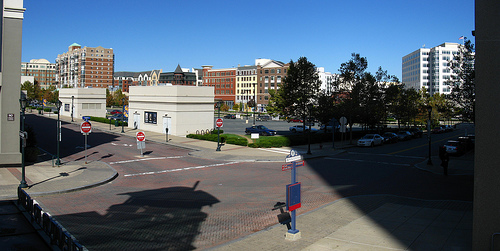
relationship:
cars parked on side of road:
[355, 115, 446, 151] [30, 114, 467, 241]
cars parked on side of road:
[444, 125, 472, 160] [30, 114, 467, 241]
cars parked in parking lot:
[244, 124, 277, 136] [215, 105, 318, 135]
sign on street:
[134, 131, 148, 141] [64, 109, 466, 239]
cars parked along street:
[355, 133, 386, 147] [306, 133, 401, 214]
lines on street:
[120, 154, 236, 178] [140, 147, 207, 232]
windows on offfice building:
[407, 53, 447, 96] [398, 39, 484, 111]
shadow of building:
[309, 127, 419, 208] [440, 15, 485, 245]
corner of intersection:
[0, 160, 120, 206] [128, 139, 254, 248]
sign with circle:
[80, 121, 94, 135] [78, 118, 92, 129]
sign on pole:
[274, 146, 298, 182] [286, 151, 313, 234]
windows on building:
[221, 69, 269, 92] [213, 49, 292, 65]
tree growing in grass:
[264, 56, 324, 132] [261, 123, 317, 148]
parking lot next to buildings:
[218, 108, 280, 147] [205, 66, 288, 114]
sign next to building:
[65, 111, 96, 176] [13, 43, 23, 184]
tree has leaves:
[264, 56, 324, 132] [283, 86, 320, 114]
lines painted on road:
[109, 140, 219, 186] [134, 169, 216, 240]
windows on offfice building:
[411, 54, 461, 97] [402, 41, 475, 117]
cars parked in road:
[244, 124, 277, 136] [336, 142, 421, 198]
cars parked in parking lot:
[235, 117, 310, 137] [231, 107, 294, 130]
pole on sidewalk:
[276, 145, 304, 238] [319, 180, 414, 250]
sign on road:
[129, 133, 148, 154] [111, 170, 191, 240]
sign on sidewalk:
[73, 114, 98, 164] [318, 200, 409, 246]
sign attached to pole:
[215, 118, 226, 129] [215, 124, 224, 150]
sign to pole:
[282, 160, 307, 171] [283, 106, 321, 179]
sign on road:
[134, 131, 148, 141] [55, 102, 330, 247]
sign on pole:
[282, 160, 307, 171] [258, 170, 324, 235]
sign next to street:
[282, 160, 307, 171] [31, 119, 454, 249]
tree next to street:
[275, 53, 326, 141] [31, 119, 454, 249]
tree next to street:
[311, 49, 381, 139] [31, 119, 454, 249]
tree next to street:
[385, 82, 417, 132] [87, 118, 464, 230]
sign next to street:
[134, 131, 148, 141] [20, 137, 475, 237]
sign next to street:
[215, 118, 226, 129] [22, 118, 480, 239]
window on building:
[442, 47, 452, 54] [396, 40, 471, 100]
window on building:
[423, 63, 431, 68] [401, 40, 467, 100]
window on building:
[444, 84, 452, 92] [398, 38, 472, 94]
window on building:
[419, 55, 428, 61] [396, 40, 471, 100]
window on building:
[411, 70, 416, 72] [396, 45, 456, 97]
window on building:
[431, 79, 439, 88] [404, 41, 464, 101]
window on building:
[271, 79, 283, 86] [258, 59, 301, 113]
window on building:
[272, 80, 283, 88] [255, 59, 307, 123]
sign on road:
[215, 118, 226, 129] [0, 110, 476, 251]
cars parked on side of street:
[355, 133, 386, 147] [64, 129, 371, 248]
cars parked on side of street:
[440, 140, 467, 154] [20, 137, 475, 237]